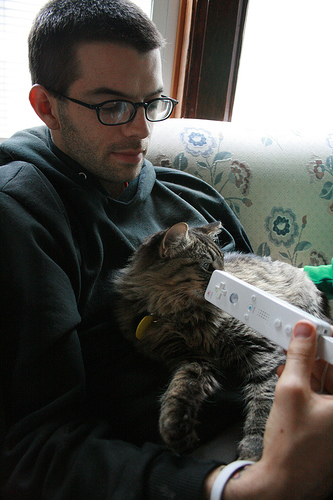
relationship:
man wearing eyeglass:
[29, 0, 191, 236] [77, 96, 177, 144]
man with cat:
[29, 0, 191, 236] [107, 195, 286, 440]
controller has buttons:
[201, 276, 330, 362] [212, 279, 265, 329]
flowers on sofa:
[217, 158, 294, 236] [198, 133, 319, 274]